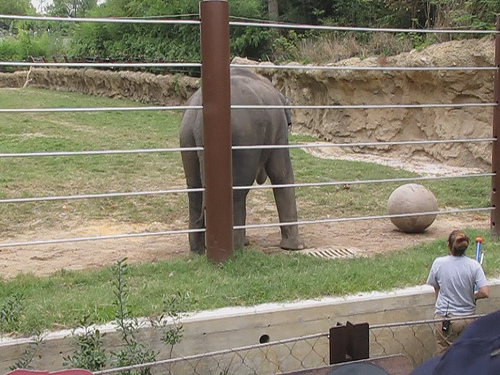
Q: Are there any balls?
A: Yes, there is a ball.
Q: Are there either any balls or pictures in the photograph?
A: Yes, there is a ball.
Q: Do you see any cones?
A: No, there are no cones.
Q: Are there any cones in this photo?
A: No, there are no cones.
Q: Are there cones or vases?
A: No, there are no cones or vases.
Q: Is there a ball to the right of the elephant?
A: Yes, there is a ball to the right of the elephant.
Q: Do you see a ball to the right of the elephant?
A: Yes, there is a ball to the right of the elephant.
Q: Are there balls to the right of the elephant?
A: Yes, there is a ball to the right of the elephant.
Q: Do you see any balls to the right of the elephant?
A: Yes, there is a ball to the right of the elephant.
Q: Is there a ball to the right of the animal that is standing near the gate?
A: Yes, there is a ball to the right of the elephant.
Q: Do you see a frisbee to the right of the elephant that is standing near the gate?
A: No, there is a ball to the right of the elephant.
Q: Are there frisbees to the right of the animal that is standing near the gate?
A: No, there is a ball to the right of the elephant.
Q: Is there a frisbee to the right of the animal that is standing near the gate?
A: No, there is a ball to the right of the elephant.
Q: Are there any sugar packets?
A: No, there are no sugar packets.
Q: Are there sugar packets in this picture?
A: No, there are no sugar packets.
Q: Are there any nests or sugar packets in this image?
A: No, there are no sugar packets or nests.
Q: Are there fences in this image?
A: Yes, there is a fence.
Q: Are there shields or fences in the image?
A: Yes, there is a fence.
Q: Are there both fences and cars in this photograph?
A: No, there is a fence but no cars.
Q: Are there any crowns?
A: No, there are no crowns.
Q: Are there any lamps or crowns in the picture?
A: No, there are no crowns or lamps.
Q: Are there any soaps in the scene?
A: No, there are no soaps.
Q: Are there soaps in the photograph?
A: No, there are no soaps.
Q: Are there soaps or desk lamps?
A: No, there are no soaps or desk lamps.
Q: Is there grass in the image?
A: Yes, there is grass.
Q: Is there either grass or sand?
A: Yes, there is grass.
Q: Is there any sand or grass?
A: Yes, there is grass.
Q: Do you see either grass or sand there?
A: Yes, there is grass.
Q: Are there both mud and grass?
A: No, there is grass but no mud.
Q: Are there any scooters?
A: No, there are no scooters.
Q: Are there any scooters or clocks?
A: No, there are no scooters or clocks.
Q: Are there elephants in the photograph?
A: Yes, there is an elephant.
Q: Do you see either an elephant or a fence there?
A: Yes, there is an elephant.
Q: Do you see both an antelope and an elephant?
A: No, there is an elephant but no antelopes.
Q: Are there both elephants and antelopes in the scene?
A: No, there is an elephant but no antelopes.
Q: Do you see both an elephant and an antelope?
A: No, there is an elephant but no antelopes.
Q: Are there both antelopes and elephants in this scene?
A: No, there is an elephant but no antelopes.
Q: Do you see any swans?
A: No, there are no swans.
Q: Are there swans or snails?
A: No, there are no swans or snails.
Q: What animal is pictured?
A: The animal is an elephant.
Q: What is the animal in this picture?
A: The animal is an elephant.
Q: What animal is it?
A: The animal is an elephant.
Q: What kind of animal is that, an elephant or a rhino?
A: That is an elephant.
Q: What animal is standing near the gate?
A: The elephant is standing near the gate.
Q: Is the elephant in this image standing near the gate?
A: Yes, the elephant is standing near the gate.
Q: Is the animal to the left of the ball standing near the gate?
A: Yes, the elephant is standing near the gate.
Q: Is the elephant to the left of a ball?
A: Yes, the elephant is to the left of a ball.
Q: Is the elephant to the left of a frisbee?
A: No, the elephant is to the left of a ball.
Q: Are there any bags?
A: No, there are no bags.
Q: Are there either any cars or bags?
A: No, there are no bags or cars.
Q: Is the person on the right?
A: Yes, the person is on the right of the image.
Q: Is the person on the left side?
A: No, the person is on the right of the image.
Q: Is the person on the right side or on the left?
A: The person is on the right of the image.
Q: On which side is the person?
A: The person is on the right of the image.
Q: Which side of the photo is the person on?
A: The person is on the right of the image.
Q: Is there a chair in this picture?
A: No, there are no chairs.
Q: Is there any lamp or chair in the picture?
A: No, there are no chairs or lamps.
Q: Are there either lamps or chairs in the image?
A: No, there are no chairs or lamps.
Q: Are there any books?
A: No, there are no books.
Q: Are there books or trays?
A: No, there are no books or trays.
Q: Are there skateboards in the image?
A: No, there are no skateboards.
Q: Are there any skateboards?
A: No, there are no skateboards.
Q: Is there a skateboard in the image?
A: No, there are no skateboards.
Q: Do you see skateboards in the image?
A: No, there are no skateboards.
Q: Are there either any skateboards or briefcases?
A: No, there are no skateboards or briefcases.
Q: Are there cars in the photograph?
A: No, there are no cars.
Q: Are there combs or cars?
A: No, there are no cars or combs.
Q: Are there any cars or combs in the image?
A: No, there are no cars or combs.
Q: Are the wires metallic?
A: Yes, the wires are metallic.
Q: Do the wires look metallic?
A: Yes, the wires are metallic.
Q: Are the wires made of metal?
A: Yes, the wires are made of metal.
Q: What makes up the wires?
A: The wires are made of metal.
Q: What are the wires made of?
A: The wires are made of metal.